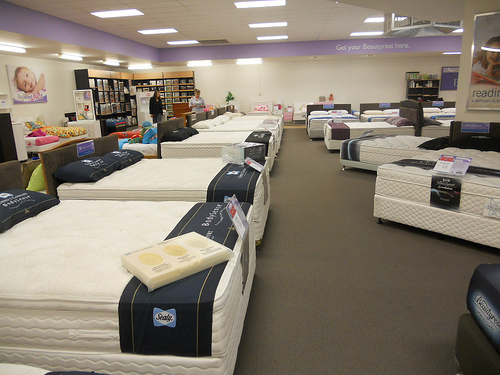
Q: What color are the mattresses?
A: White.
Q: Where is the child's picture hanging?
A: Left wall.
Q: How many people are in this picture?
A: 2.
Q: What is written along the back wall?
A: Get your beautyrest here.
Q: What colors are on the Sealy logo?
A: Blue, white, black.